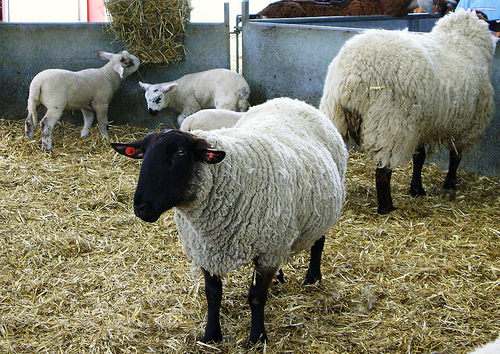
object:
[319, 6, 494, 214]
sheep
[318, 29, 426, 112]
backside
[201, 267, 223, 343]
sheep's legs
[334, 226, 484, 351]
hay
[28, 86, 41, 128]
lamb's tail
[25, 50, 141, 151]
lamb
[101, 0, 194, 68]
hay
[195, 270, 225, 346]
front leg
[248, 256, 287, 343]
front leg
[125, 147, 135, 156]
tag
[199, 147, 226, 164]
left ear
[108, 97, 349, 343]
lamb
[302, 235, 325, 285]
back leg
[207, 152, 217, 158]
tag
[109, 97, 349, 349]
sheep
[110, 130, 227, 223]
head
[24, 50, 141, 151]
lambs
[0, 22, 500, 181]
stall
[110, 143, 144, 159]
ears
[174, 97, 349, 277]
coat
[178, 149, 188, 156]
eye